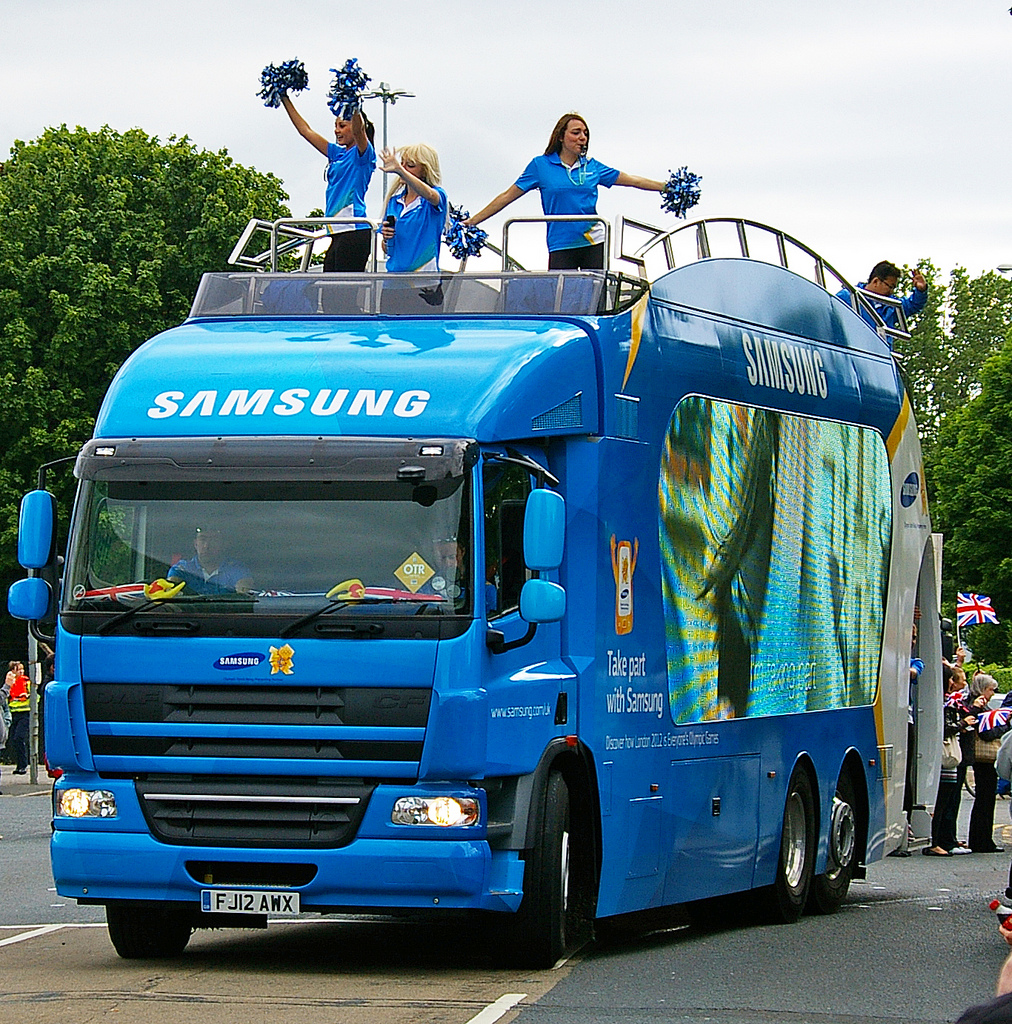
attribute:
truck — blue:
[91, 131, 909, 986]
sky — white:
[32, 33, 856, 270]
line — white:
[430, 990, 510, 1021]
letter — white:
[174, 366, 190, 421]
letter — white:
[161, 281, 251, 446]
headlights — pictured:
[49, 778, 463, 836]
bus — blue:
[8, 184, 937, 977]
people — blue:
[275, 75, 626, 247]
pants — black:
[920, 748, 980, 845]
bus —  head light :
[400, 782, 477, 855]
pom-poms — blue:
[256, 57, 313, 106]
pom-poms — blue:
[324, 55, 368, 123]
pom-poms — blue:
[668, 165, 702, 225]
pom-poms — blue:
[436, 195, 487, 270]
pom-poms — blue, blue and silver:
[322, 49, 373, 122]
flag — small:
[951, 701, 1006, 735]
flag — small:
[946, 585, 999, 680]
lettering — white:
[142, 382, 438, 415]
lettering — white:
[736, 327, 844, 398]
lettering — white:
[598, 642, 656, 686]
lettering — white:
[602, 690, 675, 717]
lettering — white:
[591, 714, 730, 758]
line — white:
[460, 942, 585, 1019]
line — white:
[2, 920, 57, 947]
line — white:
[258, 910, 357, 926]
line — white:
[0, 914, 110, 932]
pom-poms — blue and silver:
[657, 156, 706, 220]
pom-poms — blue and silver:
[444, 198, 493, 275]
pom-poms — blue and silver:
[256, 46, 313, 110]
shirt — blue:
[521, 149, 624, 248]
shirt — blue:
[372, 184, 452, 270]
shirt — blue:
[311, 139, 373, 231]